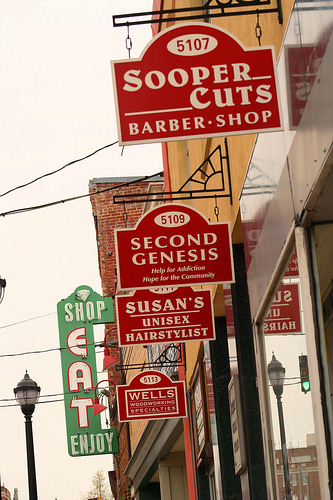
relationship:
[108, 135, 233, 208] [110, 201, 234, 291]
hanger for sign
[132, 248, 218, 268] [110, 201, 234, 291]
word on a sign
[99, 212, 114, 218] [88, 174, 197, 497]
brick on a building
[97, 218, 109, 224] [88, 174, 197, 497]
brick on a building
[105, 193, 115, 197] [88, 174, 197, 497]
brick on a building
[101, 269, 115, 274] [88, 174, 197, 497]
brick on a building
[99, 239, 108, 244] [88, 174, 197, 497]
brick on a building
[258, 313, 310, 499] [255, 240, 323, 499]
reflection on window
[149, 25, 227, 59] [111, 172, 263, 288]
number on a sign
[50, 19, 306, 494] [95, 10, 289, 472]
sign in a row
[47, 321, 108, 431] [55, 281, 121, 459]
word on a sign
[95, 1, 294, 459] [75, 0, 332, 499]
yellow side of a building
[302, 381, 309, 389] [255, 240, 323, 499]
light in window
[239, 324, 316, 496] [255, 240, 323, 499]
lamp in window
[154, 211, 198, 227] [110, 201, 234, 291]
red numbers on a sign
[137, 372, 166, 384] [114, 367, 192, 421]
red numbers on a sign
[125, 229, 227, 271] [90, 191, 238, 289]
letters on sign